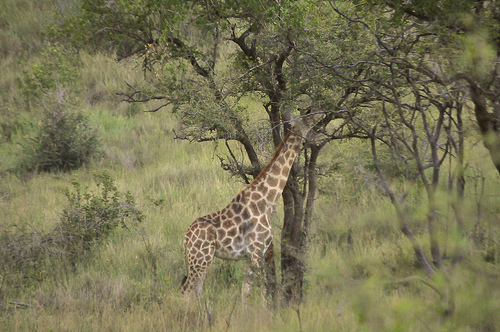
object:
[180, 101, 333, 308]
giraffe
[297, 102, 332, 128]
head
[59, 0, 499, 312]
trees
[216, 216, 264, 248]
spots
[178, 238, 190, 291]
tail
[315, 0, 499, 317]
tree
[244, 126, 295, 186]
hair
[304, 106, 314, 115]
eye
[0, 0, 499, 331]
grass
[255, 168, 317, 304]
base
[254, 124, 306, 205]
neck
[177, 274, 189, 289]
tip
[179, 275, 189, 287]
hair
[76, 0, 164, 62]
branches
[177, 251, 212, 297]
hind leg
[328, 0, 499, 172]
tree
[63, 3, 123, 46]
leaves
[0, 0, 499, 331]
field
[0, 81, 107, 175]
bush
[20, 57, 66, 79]
leaves